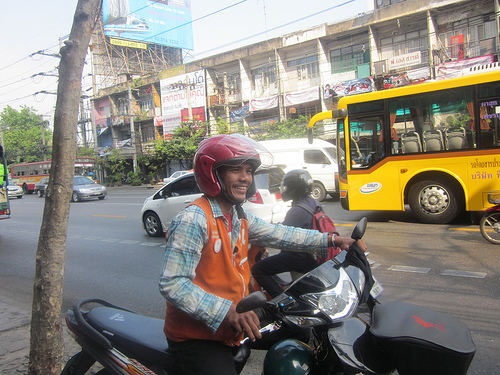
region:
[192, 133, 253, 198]
the man is wearing a helmet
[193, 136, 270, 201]
the helmet is red in color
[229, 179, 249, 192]
the man has a broad smile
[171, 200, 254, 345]
the man is wearing a vest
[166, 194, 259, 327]
the vest is orange in color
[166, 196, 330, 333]
the man is wearing a long sleeve shirt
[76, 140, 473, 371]
the man is on a motorcycle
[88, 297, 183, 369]
the seat is black in color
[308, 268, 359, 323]
a head light is on the motorcycle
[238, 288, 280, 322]
the mirror is black in color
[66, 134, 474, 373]
man on a motorcycle on the sidewalk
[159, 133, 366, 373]
man in red helmet and orange vest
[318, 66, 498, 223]
yellow bus in the street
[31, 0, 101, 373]
tree trunk next to motorcycle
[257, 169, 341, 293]
man on motorcycle in street with red backpack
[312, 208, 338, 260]
red backpack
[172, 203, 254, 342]
man's orange vest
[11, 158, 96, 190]
red and orange bus in the distance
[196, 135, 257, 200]
red motorcycle helmet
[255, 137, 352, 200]
white van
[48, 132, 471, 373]
the man is on a motorcycle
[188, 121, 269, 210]
the man is wearing a helmet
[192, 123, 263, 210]
the mans helmet is red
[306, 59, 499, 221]
a bus is in the background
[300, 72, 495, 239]
the bus in the background is yellow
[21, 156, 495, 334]
the road the vehicles are traveling on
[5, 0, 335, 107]
power lines are above the road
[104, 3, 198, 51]
a billboard is in the background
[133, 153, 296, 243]
the vehicle on the road is white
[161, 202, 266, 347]
the man is wearing an orange vest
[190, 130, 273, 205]
this motorcyclist is wearing a red helmet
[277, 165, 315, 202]
this motorcyclist is wearing a black helmet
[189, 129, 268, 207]
this motorcyclist is smiling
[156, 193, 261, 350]
this motorcyclist is wearing an orange vest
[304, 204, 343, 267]
this motorcyclist is wearing a backpack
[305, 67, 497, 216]
this bus is bright yellow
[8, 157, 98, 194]
there is a red bus down the street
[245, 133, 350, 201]
there is a white van near the yellow bus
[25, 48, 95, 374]
a tree is planted at curbside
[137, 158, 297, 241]
a white car passes behind the motorcyclists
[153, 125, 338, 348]
Man on a scooter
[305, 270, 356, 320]
headlight on a scooter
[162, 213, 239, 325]
Man with a plaid shirt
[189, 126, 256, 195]
man with a red helmet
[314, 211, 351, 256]
man wearing a red backpack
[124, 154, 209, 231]
white car on the street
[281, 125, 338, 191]
white van on the street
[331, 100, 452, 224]
yellow bus on the street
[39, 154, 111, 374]
Tree next to a scooter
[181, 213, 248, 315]
man wearing a orange street